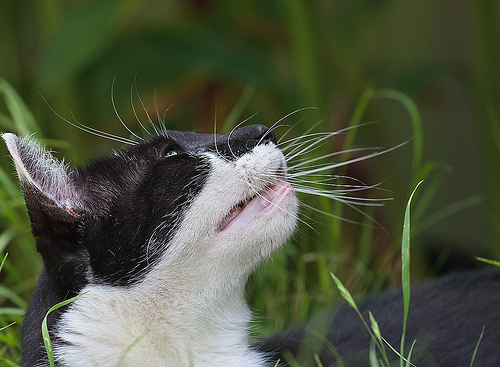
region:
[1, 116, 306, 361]
black and white cat looking up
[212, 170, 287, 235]
pink lips and gums on open mouth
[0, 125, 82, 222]
grey hairs extending from pointy ear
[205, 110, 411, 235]
white whiskers from bottom of black nose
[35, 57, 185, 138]
long white hairs from top of eye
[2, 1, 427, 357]
green blades of grass surrounding cat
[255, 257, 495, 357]
black cat body with fur slanting in one direction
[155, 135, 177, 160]
triangular eye reflecting light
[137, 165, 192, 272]
white hairs over edge of black marking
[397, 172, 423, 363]
curved blade of upright grass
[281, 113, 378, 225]
cat's white whiskers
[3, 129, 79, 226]
cat's black and white ear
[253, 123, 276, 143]
cat's black nose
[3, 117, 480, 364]
black and white cat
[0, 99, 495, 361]
cat laying in the grass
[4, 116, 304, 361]
cat looking up toward the sky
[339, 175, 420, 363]
blades of grass in front of the cat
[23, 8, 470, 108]
out of focus background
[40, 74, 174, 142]
whiskers above the cat's eye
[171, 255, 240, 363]
white fur on the cat's neck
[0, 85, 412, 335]
the catr is looking up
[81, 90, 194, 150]
the cat has long whiskers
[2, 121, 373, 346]
the cat is black and white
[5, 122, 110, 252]
the cat has an ear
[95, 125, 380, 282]
the cats mouth is pink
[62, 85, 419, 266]
the cats whiskers are white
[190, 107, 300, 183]
the cats nose is black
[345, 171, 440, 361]
the blade of grass is tall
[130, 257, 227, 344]
the cats fur is white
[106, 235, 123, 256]
the cats fur is black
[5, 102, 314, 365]
black and white cat in green field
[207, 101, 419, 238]
white whiskers on face of cat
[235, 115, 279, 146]
black cat nose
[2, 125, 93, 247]
pointed cat ear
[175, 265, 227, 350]
white cat fur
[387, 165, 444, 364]
blade of green grass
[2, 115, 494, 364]
cat lying in green grass looking up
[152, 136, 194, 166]
one cat eye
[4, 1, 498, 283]
blurred green grass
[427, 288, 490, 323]
blurred texture of black cat fur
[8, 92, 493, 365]
a black and white cat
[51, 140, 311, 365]
white portion of cat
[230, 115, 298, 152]
black nose on cat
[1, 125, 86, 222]
white tipped ear of cat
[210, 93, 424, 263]
white whiskers on cat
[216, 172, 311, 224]
pink in the mouth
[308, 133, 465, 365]
grass stands in front of cat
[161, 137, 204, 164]
partial eye of cat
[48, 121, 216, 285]
black fur on face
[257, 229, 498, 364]
black body of cat